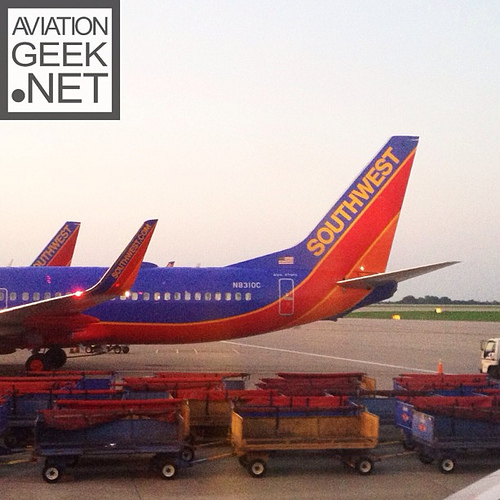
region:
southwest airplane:
[2, 136, 422, 351]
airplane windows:
[141, 290, 253, 302]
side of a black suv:
[34, 419, 198, 481]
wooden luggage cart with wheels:
[231, 406, 378, 473]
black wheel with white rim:
[440, 455, 460, 472]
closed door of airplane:
[276, 277, 296, 319]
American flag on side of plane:
[272, 252, 296, 268]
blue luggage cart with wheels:
[395, 399, 498, 474]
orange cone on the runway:
[427, 352, 445, 375]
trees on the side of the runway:
[402, 290, 497, 308]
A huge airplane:
[0, 132, 462, 372]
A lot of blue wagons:
[4, 359, 499, 472]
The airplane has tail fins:
[7, 130, 461, 372]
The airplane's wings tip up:
[5, 215, 160, 338]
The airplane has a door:
[1, 127, 459, 375]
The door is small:
[272, 272, 304, 327]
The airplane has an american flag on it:
[0, 123, 465, 372]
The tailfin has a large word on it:
[297, 131, 462, 382]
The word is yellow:
[301, 141, 406, 263]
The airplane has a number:
[1, 132, 470, 374]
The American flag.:
[263, 246, 294, 267]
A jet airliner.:
[10, 116, 460, 347]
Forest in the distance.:
[400, 290, 495, 305]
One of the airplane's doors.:
[270, 270, 297, 321]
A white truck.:
[472, 320, 494, 377]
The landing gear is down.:
[11, 340, 81, 382]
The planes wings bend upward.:
[25, 200, 271, 330]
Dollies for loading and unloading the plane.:
[10, 355, 495, 480]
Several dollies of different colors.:
[5, 360, 495, 462]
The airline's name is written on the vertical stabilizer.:
[293, 136, 403, 264]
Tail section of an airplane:
[308, 129, 467, 336]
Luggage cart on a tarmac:
[226, 402, 386, 481]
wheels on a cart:
[241, 452, 271, 482]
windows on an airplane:
[178, 281, 225, 311]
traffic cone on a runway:
[421, 348, 453, 382]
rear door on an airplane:
[269, 270, 309, 334]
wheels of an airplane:
[15, 333, 79, 385]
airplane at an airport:
[3, 126, 460, 371]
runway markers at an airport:
[386, 295, 463, 341]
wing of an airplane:
[4, 213, 161, 338]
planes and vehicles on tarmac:
[53, 55, 449, 467]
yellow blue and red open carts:
[205, 362, 490, 477]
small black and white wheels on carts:
[40, 450, 470, 480]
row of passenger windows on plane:
[135, 290, 270, 302]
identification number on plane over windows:
[217, 272, 262, 292]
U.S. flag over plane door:
[265, 245, 300, 265]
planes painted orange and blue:
[15, 210, 441, 336]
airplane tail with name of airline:
[296, 136, 433, 277]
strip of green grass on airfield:
[340, 290, 492, 331]